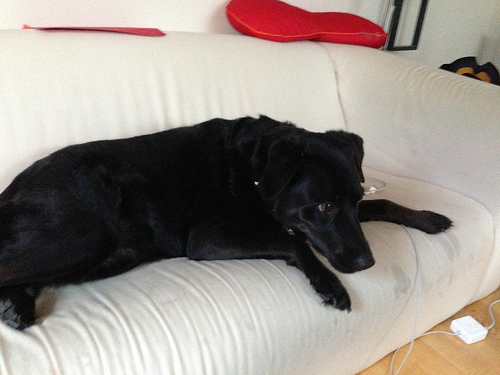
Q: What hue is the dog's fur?
A: Black.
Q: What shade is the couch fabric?
A: White.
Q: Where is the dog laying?
A: On couch.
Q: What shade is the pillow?
A: Red.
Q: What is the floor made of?
A: Wood.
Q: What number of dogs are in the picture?
A: One.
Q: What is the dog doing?
A: Laying on the couch.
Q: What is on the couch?
A: A dog.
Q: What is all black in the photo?
A: The dog.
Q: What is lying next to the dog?
A: A laptop charger.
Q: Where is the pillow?
A: On top of the couch.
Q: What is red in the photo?
A: A pillow.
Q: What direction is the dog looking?
A: Down.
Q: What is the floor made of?
A: Wood.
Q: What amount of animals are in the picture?
A: 1.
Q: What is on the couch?
A: A black dog.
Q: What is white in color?
A: The couch.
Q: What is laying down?
A: The dog.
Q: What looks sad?
A: The dog.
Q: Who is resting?
A: The dog.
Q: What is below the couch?
A: The floor.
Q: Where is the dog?
A: On a couch.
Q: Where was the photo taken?
A: In a room.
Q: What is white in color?
A: Couch.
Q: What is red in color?
A: Pillow.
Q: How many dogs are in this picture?
A: 1.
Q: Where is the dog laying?
A: On couch.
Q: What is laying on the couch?
A: Dog.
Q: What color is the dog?
A: Black.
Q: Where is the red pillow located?
A: Top of couch.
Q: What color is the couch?
A: White.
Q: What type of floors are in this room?
A: Wood.